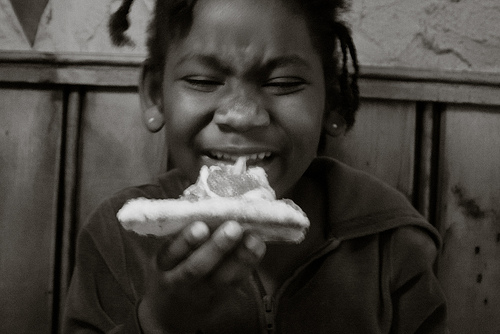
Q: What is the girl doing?
A: Eating.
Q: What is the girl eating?
A: Pizza.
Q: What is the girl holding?
A: A piece of pizza.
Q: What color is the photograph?
A: Black and white.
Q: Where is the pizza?
A: In the girl's hand.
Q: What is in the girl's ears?
A: Earrings.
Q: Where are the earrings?
A: In the girl's ears.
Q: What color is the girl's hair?
A: Black.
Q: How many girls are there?
A: One.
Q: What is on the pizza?
A: Pepperoni.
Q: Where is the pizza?
A: Girl's right hand.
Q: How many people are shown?
A: 1.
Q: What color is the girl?
A: Black.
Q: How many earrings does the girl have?
A: 2.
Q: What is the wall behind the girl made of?
A: Wood.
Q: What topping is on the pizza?
A: Pepperoni.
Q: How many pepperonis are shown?
A: 2.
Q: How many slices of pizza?
A: 1.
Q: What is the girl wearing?
A: Sweatshirt.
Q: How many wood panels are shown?
A: 4.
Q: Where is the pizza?
A: In the girl's hand.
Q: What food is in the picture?
A: Pizza.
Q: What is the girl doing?
A: Eating.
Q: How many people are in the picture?
A: One.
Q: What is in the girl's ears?
A: Earrings.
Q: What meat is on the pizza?
A: Pepperoni.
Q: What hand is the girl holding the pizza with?
A: Right.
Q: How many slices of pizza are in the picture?
A: One.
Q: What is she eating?
A: Pizza.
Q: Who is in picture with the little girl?
A: No one.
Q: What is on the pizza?
A: Cheese and pepperoni.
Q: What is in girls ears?
A: Earrings.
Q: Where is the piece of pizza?
A: In girls hand.